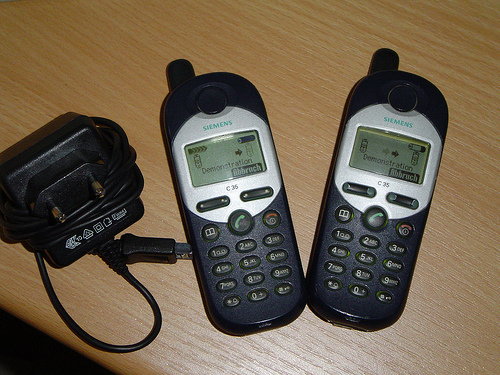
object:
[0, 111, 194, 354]
cable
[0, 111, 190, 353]
charger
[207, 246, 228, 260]
button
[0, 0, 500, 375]
ground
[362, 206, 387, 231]
button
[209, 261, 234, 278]
buttons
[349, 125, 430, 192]
screen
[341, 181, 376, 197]
buttons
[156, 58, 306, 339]
black phone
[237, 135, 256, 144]
battery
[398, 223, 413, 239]
button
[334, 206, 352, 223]
button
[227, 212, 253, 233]
button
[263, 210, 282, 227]
button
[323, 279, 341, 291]
button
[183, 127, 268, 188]
information window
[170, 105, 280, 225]
frame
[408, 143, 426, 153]
battery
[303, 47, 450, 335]
black phone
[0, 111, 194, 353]
adapter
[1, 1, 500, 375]
table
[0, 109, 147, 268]
battery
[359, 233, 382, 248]
button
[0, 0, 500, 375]
surface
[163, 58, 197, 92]
antennas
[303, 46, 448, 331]
plane